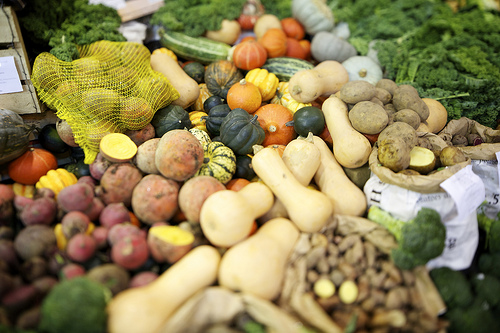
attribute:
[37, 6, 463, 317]
vegetables — assortment of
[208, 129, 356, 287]
squash — several of, in middle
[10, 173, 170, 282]
potatoes — bunch of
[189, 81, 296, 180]
pumpkins — decorative, in middle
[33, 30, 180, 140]
potatoes — bag of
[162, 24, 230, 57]
zucchini — single, near back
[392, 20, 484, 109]
vegetable — leafy, in corner right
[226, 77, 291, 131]
oranges — in middle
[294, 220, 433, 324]
legumes — mix of, small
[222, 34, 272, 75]
goard — orange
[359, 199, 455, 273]
broccoli — green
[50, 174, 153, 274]
veggies — round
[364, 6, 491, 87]
veggies — green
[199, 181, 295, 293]
squash — light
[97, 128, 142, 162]
food — cut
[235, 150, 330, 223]
squash — vegetables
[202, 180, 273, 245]
squash — vegetables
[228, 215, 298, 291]
squash — vegetables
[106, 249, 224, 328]
squash — vegetables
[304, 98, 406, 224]
squash — vegetables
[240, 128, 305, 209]
squash — vegetables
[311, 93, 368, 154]
squash — vegetables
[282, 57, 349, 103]
squash — vegetables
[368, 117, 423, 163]
potato — vegetables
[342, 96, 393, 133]
potato — vegetables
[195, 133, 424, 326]
group — vegetables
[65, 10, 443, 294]
view — mixed, vegetables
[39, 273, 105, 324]
leafs — part, green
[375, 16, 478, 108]
veges — green, side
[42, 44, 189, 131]
nut — top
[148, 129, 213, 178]
pile — big, vegetable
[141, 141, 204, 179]
pile — vegetable, big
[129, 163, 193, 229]
pile — big, vegetable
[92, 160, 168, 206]
pile — vegetable, big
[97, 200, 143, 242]
pile — big, vegetable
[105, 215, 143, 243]
pile — vegetable, big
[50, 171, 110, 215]
pile — big, vegetable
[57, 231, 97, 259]
pile — vegetable, big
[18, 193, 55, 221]
pile — big, vegetable